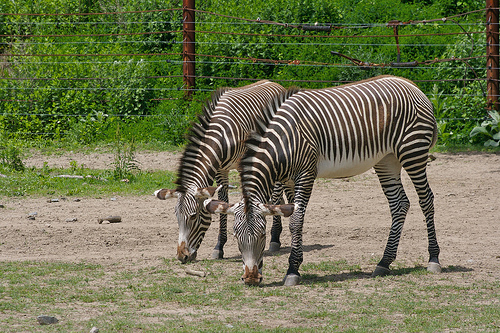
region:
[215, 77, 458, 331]
a zebra standing outside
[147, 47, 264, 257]
a zebra standing outside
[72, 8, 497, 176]
a wire fence with wood poles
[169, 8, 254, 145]
a wood fence pole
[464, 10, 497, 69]
a wood fence pole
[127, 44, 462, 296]
two zebras eating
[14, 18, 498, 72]
a wire fence in back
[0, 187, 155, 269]
a brown bare spot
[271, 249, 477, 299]
a shadow on the ground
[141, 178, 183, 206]
the right ear on a zebra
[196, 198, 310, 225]
the top of zebra's head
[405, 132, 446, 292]
a zebra's left back leg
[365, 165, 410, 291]
a zebra's right back leg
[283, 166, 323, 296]
a zebra's front leg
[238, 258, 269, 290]
the zebra's pink nose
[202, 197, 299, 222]
perfectly spread ears of a zebra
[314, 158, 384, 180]
the white underbelly of a zebra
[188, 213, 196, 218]
the black eye of a zebra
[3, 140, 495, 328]
grass and gray dirt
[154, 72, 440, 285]
two zebras grazing on grass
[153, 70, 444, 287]
two zebras facing left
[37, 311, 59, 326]
a sharp gray stone on the ground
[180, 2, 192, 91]
a brown wooden post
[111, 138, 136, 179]
two tall green weeds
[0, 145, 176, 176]
a gray path behind two zebras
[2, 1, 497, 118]
wire on rusted poles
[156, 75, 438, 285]
two zebra grazing on grass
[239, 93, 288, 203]
man on zebra neck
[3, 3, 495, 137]
green leaves of vegetation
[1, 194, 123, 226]
rocks on dirt ground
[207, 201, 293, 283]
horizontal ears on head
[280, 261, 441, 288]
hooves on zebra legs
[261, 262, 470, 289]
zebra shadow on ground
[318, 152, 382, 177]
white belly of zebra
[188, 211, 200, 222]
eye on zebra head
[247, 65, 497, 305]
a zebra standing in a field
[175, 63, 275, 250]
a zebra standing in a field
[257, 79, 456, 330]
a zebra eating grass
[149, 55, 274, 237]
a zebra eating grass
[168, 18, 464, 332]
two zebras standing in a field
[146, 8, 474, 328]
two zebras eating grass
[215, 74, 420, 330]
zebra with head down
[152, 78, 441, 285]
Two zebras eating grass.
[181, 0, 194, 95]
A brown fence post.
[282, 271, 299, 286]
The zebra's left hoof.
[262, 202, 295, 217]
The zebra's left ear.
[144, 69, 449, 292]
two zebras grazing on grass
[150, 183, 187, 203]
ear on head of zebra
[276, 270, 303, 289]
grey hoof of zebra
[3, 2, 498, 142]
metal fence behind zebra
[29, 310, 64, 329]
grey rock on ground in front of zebra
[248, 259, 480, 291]
shadow of zebra on ground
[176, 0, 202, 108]
brown metal fence support pole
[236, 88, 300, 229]
black and white striped zebra mane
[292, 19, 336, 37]
black object on metal fence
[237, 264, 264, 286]
brown nose of zebra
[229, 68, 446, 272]
An animal in a field.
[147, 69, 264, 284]
An animal in a field.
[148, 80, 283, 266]
A zebra in a field.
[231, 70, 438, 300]
A zebra in a field.